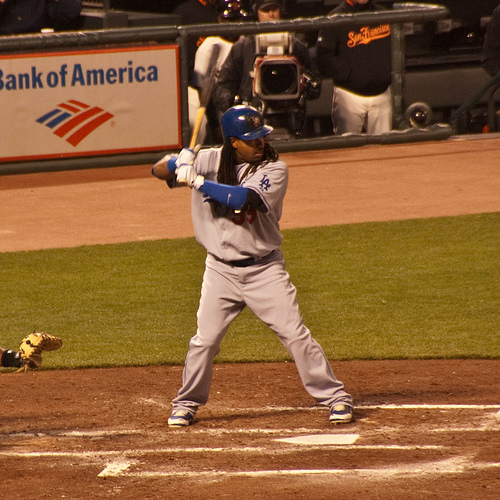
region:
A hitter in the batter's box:
[143, 42, 362, 437]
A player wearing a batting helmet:
[216, 100, 277, 164]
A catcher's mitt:
[15, 325, 67, 373]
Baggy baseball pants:
[162, 253, 362, 426]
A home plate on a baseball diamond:
[265, 426, 363, 453]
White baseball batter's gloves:
[168, 144, 200, 192]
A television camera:
[250, 29, 321, 144]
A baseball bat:
[185, 40, 225, 162]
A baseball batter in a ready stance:
[146, 40, 361, 430]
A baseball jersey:
[164, 140, 294, 265]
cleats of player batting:
[168, 400, 355, 424]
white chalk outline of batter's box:
[5, 383, 499, 492]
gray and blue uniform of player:
[165, 144, 347, 399]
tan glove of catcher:
[17, 328, 59, 369]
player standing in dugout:
[320, 4, 404, 136]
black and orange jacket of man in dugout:
[317, 3, 397, 95]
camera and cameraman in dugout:
[228, 6, 315, 129]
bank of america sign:
[0, 50, 186, 158]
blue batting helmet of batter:
[211, 105, 269, 135]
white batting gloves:
[170, 144, 202, 186]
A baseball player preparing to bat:
[152, 105, 359, 429]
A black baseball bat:
[186, 64, 225, 151]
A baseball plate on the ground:
[271, 430, 362, 445]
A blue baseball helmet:
[221, 104, 274, 141]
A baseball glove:
[18, 328, 62, 371]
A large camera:
[252, 31, 307, 136]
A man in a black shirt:
[317, 2, 395, 134]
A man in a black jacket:
[217, 0, 317, 140]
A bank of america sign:
[1, 43, 182, 161]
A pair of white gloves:
[175, 145, 201, 185]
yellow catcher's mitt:
[16, 328, 65, 373]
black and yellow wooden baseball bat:
[176, 33, 223, 185]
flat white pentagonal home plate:
[266, 427, 365, 447]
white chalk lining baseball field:
[1, 391, 498, 481]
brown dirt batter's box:
[0, 356, 498, 498]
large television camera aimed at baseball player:
[238, 28, 321, 133]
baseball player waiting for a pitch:
[149, 101, 357, 429]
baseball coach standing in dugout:
[311, 0, 411, 150]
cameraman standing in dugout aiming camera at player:
[211, 0, 323, 165]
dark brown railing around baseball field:
[0, 1, 460, 178]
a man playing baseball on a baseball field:
[147, 45, 360, 427]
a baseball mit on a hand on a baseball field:
[12, 323, 64, 374]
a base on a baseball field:
[263, 426, 366, 450]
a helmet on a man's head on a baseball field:
[217, 101, 282, 143]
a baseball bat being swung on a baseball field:
[178, 43, 225, 154]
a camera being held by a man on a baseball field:
[240, 33, 326, 110]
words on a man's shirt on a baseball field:
[335, 22, 401, 51]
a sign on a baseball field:
[0, 39, 189, 165]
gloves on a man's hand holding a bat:
[170, 143, 209, 195]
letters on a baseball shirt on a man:
[255, 170, 276, 194]